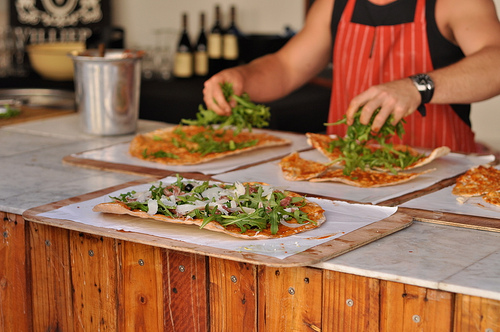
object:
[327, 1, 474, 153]
apron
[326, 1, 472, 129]
tank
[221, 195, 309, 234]
vegetable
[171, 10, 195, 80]
bottle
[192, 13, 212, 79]
bottle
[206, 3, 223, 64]
bottle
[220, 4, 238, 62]
bottle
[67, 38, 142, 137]
container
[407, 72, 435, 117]
watch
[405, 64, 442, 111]
wrist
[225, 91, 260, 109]
vegetables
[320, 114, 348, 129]
vegetables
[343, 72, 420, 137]
hand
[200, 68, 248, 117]
hand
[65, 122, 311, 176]
pizza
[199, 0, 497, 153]
chef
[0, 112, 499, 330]
counter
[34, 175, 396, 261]
paper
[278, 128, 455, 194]
tortilla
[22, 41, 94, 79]
bowl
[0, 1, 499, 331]
kitchen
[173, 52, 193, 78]
label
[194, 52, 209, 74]
label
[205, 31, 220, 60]
label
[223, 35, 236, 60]
label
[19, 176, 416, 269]
board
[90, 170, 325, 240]
tortilla